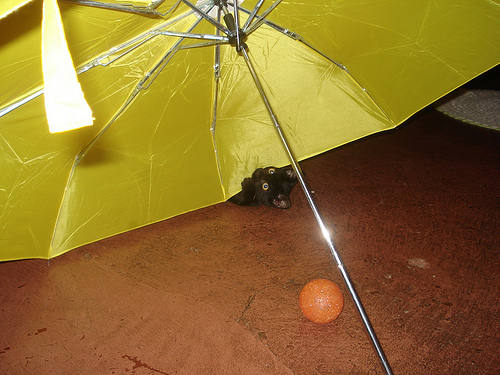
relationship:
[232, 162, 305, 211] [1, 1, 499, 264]
cat under umbrella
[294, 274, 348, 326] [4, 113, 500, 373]
ball on ground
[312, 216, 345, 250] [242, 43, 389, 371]
light on handle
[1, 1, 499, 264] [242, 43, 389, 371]
umbrella has handle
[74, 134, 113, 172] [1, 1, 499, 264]
shadow on umbrella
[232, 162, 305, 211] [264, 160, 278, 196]
cat has eyes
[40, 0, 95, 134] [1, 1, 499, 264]
frame hanging on umbrella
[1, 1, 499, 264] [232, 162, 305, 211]
umbrella on cat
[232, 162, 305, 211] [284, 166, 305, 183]
cat has ear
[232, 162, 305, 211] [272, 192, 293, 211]
cat has ear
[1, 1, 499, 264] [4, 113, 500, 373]
umbrella on ground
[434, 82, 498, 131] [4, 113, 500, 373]
mat on ground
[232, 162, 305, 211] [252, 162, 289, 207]
cat has head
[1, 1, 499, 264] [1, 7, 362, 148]
umbrella has frame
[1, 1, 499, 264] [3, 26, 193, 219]
umbrella has wrinkles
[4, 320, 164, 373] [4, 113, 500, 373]
spots on ground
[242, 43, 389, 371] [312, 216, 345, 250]
handle has light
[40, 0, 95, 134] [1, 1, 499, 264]
frame on umbrella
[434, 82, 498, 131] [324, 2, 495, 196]
mat in corner